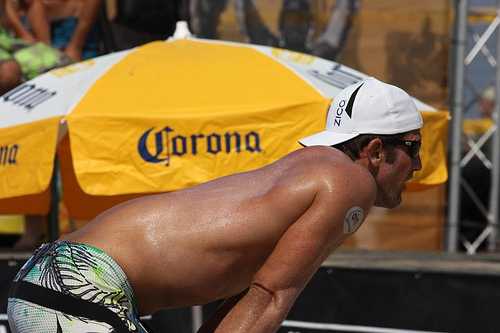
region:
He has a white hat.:
[288, 64, 428, 141]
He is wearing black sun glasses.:
[388, 131, 433, 152]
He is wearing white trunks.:
[3, 216, 149, 331]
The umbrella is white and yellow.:
[14, 39, 444, 173]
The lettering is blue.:
[128, 125, 275, 155]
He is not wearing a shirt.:
[39, 151, 424, 331]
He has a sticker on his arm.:
[334, 196, 366, 237]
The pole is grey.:
[448, 2, 469, 278]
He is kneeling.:
[21, 96, 423, 331]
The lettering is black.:
[313, 84, 361, 135]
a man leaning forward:
[15, 73, 423, 330]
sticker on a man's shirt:
[344, 205, 363, 236]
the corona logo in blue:
[133, 123, 265, 165]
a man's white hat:
[295, 75, 424, 151]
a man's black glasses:
[387, 133, 421, 158]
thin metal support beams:
[450, 5, 498, 222]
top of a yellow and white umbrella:
[2, 14, 450, 215]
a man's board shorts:
[7, 240, 139, 332]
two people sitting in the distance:
[0, 0, 100, 77]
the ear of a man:
[365, 138, 385, 169]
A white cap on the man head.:
[284, 87, 432, 152]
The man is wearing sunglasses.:
[371, 130, 434, 160]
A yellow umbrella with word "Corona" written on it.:
[35, 44, 383, 173]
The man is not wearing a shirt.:
[104, 169, 381, 269]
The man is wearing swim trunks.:
[10, 226, 130, 317]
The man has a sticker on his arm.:
[337, 190, 370, 237]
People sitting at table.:
[13, 10, 113, 72]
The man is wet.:
[98, 143, 386, 284]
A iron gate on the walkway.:
[426, 10, 498, 264]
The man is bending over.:
[71, 163, 433, 305]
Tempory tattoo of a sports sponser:
[337, 201, 366, 238]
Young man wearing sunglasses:
[317, 73, 425, 207]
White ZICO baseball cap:
[290, 68, 426, 154]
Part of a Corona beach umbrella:
[0, 18, 284, 198]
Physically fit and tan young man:
[2, 75, 429, 330]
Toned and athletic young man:
[2, 72, 427, 329]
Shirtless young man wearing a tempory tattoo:
[0, 78, 427, 332]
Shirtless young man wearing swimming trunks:
[1, 75, 428, 331]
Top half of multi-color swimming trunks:
[4, 235, 138, 331]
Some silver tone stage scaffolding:
[446, 3, 498, 259]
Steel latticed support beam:
[446, 4, 498, 255]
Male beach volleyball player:
[3, 66, 432, 331]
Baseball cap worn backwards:
[296, 82, 428, 148]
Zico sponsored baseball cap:
[324, 91, 351, 129]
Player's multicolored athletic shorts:
[3, 227, 155, 329]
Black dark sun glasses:
[379, 135, 427, 157]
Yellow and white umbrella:
[3, 18, 436, 190]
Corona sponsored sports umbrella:
[112, 116, 281, 171]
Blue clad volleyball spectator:
[18, 6, 114, 56]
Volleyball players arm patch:
[338, 201, 370, 246]